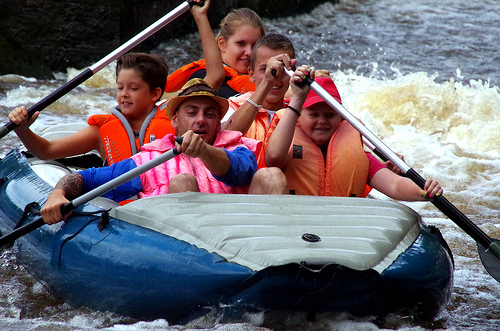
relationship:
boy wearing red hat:
[262, 64, 442, 204] [294, 73, 340, 110]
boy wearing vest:
[262, 64, 442, 204] [257, 109, 368, 195]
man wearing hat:
[38, 77, 290, 223] [165, 77, 230, 121]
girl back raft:
[161, 6, 267, 100] [1, 124, 461, 321]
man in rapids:
[38, 77, 289, 226] [356, 66, 483, 193]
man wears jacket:
[38, 77, 289, 226] [72, 130, 255, 199]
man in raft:
[38, 77, 289, 226] [150, 164, 464, 314]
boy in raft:
[262, 64, 442, 204] [150, 164, 464, 314]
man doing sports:
[38, 77, 289, 226] [2, 3, 494, 330]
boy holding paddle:
[272, 64, 447, 203] [276, 51, 498, 273]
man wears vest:
[38, 77, 289, 226] [146, 169, 168, 193]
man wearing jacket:
[38, 77, 289, 226] [72, 130, 255, 199]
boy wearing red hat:
[262, 64, 442, 204] [294, 73, 341, 105]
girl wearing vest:
[264, 67, 444, 197] [269, 119, 370, 200]